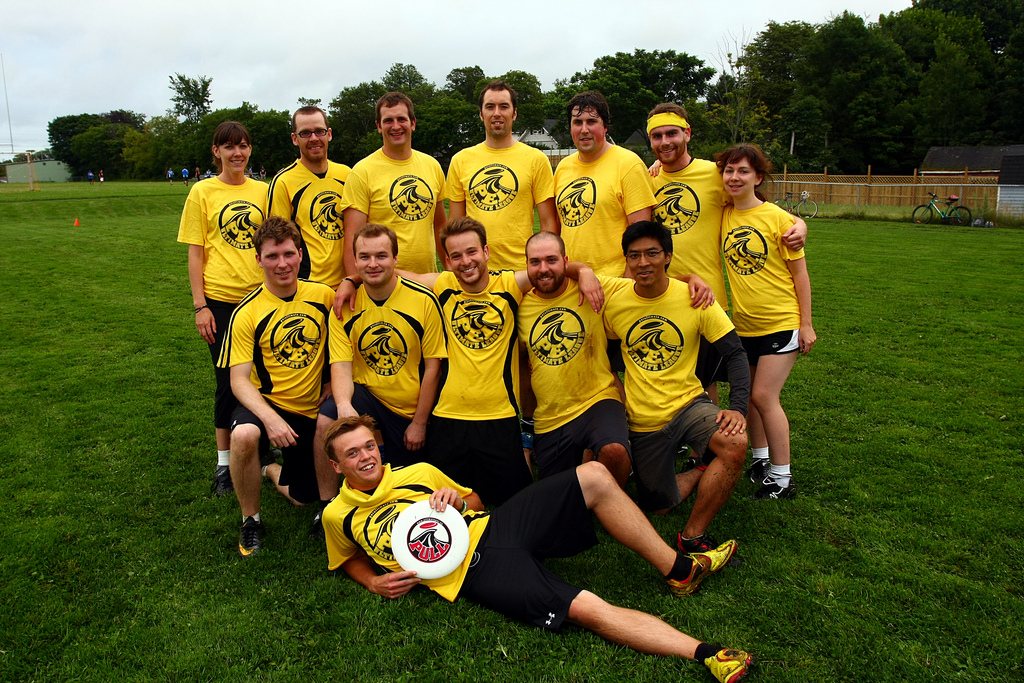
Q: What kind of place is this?
A: It is a field.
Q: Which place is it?
A: It is a field.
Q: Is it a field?
A: Yes, it is a field.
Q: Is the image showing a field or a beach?
A: It is showing a field.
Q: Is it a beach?
A: No, it is a field.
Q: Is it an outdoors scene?
A: Yes, it is outdoors.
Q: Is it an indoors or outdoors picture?
A: It is outdoors.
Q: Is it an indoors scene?
A: No, it is outdoors.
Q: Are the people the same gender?
A: No, they are both male and female.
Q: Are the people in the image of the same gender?
A: No, they are both male and female.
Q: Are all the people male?
A: No, they are both male and female.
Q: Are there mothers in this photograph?
A: No, there are no mothers.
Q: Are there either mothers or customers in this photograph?
A: No, there are no mothers or customers.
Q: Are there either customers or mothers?
A: No, there are no mothers or customers.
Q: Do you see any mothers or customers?
A: No, there are no mothers or customers.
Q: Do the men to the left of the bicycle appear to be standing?
A: Yes, the men are standing.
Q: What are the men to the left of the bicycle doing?
A: The men are standing.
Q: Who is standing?
A: The men are standing.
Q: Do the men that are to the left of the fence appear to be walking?
A: No, the men are standing.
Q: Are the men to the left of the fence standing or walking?
A: The men are standing.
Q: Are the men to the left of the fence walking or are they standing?
A: The men are standing.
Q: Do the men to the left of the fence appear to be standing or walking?
A: The men are standing.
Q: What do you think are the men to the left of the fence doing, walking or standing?
A: The men are standing.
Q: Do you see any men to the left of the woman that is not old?
A: Yes, there are men to the left of the woman.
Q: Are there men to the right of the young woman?
A: No, the men are to the left of the woman.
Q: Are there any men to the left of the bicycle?
A: Yes, there are men to the left of the bicycle.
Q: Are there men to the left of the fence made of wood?
A: Yes, there are men to the left of the fence.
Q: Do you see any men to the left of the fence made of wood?
A: Yes, there are men to the left of the fence.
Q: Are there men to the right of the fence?
A: No, the men are to the left of the fence.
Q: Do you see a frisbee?
A: Yes, there is a frisbee.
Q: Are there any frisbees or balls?
A: Yes, there is a frisbee.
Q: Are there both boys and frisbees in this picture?
A: Yes, there are both a frisbee and a boy.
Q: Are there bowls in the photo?
A: No, there are no bowls.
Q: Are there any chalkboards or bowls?
A: No, there are no bowls or chalkboards.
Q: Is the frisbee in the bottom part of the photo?
A: Yes, the frisbee is in the bottom of the image.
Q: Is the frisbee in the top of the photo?
A: No, the frisbee is in the bottom of the image.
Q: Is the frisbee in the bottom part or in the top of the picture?
A: The frisbee is in the bottom of the image.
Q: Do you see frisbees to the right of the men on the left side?
A: Yes, there is a frisbee to the right of the men.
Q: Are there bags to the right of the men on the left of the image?
A: No, there is a frisbee to the right of the men.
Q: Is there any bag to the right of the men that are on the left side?
A: No, there is a frisbee to the right of the men.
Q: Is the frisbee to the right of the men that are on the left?
A: Yes, the frisbee is to the right of the men.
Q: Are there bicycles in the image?
A: Yes, there is a bicycle.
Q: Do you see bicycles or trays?
A: Yes, there is a bicycle.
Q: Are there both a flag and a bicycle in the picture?
A: No, there is a bicycle but no flags.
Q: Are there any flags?
A: No, there are no flags.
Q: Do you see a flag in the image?
A: No, there are no flags.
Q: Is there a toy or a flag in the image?
A: No, there are no flags or toys.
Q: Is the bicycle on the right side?
A: Yes, the bicycle is on the right of the image.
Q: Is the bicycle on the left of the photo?
A: No, the bicycle is on the right of the image.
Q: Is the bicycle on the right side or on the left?
A: The bicycle is on the right of the image.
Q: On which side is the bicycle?
A: The bicycle is on the right of the image.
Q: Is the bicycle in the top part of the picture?
A: Yes, the bicycle is in the top of the image.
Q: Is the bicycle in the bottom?
A: No, the bicycle is in the top of the image.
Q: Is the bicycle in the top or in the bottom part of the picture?
A: The bicycle is in the top of the image.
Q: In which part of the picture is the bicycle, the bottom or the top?
A: The bicycle is in the top of the image.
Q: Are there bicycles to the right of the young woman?
A: Yes, there is a bicycle to the right of the woman.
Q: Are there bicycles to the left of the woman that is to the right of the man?
A: No, the bicycle is to the right of the woman.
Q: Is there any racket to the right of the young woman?
A: No, there is a bicycle to the right of the woman.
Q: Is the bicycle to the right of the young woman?
A: Yes, the bicycle is to the right of the woman.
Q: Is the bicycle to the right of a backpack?
A: No, the bicycle is to the right of the woman.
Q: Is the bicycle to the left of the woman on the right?
A: No, the bicycle is to the right of the woman.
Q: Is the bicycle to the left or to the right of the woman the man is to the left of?
A: The bicycle is to the right of the woman.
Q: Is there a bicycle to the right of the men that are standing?
A: Yes, there is a bicycle to the right of the men.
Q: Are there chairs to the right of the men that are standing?
A: No, there is a bicycle to the right of the men.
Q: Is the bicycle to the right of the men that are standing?
A: Yes, the bicycle is to the right of the men.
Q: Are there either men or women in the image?
A: Yes, there is a woman.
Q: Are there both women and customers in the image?
A: No, there is a woman but no customers.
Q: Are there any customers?
A: No, there are no customers.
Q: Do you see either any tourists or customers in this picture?
A: No, there are no customers or tourists.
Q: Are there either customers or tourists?
A: No, there are no customers or tourists.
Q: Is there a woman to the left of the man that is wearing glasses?
A: Yes, there is a woman to the left of the man.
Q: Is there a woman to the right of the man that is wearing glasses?
A: No, the woman is to the left of the man.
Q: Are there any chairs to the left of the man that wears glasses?
A: No, there is a woman to the left of the man.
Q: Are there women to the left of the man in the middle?
A: Yes, there is a woman to the left of the man.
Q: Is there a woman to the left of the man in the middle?
A: Yes, there is a woman to the left of the man.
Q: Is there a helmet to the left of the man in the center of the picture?
A: No, there is a woman to the left of the man.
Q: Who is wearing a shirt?
A: The woman is wearing a shirt.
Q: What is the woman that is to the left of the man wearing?
A: The woman is wearing a shirt.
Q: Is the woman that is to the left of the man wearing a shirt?
A: Yes, the woman is wearing a shirt.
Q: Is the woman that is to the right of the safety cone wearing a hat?
A: No, the woman is wearing a shirt.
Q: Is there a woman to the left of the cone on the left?
A: No, the woman is to the right of the cone.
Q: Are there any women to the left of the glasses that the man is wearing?
A: Yes, there is a woman to the left of the glasses.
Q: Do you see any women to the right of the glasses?
A: No, the woman is to the left of the glasses.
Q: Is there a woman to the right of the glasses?
A: No, the woman is to the left of the glasses.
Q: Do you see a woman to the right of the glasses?
A: No, the woman is to the left of the glasses.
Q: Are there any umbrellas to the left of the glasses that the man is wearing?
A: No, there is a woman to the left of the glasses.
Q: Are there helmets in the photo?
A: No, there are no helmets.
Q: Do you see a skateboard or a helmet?
A: No, there are no helmets or skateboards.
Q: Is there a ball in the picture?
A: No, there are no balls.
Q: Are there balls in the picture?
A: No, there are no balls.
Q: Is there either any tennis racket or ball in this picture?
A: No, there are no balls or rackets.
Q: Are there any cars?
A: No, there are no cars.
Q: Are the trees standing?
A: Yes, the trees are standing.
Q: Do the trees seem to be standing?
A: Yes, the trees are standing.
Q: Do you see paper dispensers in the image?
A: No, there are no paper dispensers.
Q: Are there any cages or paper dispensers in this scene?
A: No, there are no paper dispensers or cages.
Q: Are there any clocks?
A: No, there are no clocks.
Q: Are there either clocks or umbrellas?
A: No, there are no clocks or umbrellas.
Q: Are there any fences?
A: Yes, there is a fence.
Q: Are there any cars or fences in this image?
A: Yes, there is a fence.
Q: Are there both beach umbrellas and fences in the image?
A: No, there is a fence but no beach umbrellas.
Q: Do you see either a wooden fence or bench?
A: Yes, there is a wood fence.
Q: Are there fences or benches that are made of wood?
A: Yes, the fence is made of wood.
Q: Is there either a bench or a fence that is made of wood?
A: Yes, the fence is made of wood.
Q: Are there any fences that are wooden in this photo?
A: Yes, there is a wood fence.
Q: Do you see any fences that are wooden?
A: Yes, there is a wood fence.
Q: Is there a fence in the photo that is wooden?
A: Yes, there is a fence that is wooden.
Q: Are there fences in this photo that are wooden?
A: Yes, there is a fence that is wooden.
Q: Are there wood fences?
A: Yes, there is a fence that is made of wood.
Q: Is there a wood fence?
A: Yes, there is a fence that is made of wood.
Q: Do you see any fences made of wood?
A: Yes, there is a fence that is made of wood.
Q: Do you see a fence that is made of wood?
A: Yes, there is a fence that is made of wood.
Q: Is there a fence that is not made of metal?
A: Yes, there is a fence that is made of wood.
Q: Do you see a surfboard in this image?
A: No, there are no surfboards.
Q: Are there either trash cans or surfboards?
A: No, there are no surfboards or trash cans.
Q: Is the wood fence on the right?
A: Yes, the fence is on the right of the image.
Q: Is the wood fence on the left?
A: No, the fence is on the right of the image.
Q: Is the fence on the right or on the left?
A: The fence is on the right of the image.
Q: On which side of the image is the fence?
A: The fence is on the right of the image.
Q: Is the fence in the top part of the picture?
A: Yes, the fence is in the top of the image.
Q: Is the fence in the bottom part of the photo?
A: No, the fence is in the top of the image.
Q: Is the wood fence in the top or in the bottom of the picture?
A: The fence is in the top of the image.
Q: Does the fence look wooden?
A: Yes, the fence is wooden.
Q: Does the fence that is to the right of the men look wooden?
A: Yes, the fence is wooden.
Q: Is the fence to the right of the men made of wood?
A: Yes, the fence is made of wood.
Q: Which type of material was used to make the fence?
A: The fence is made of wood.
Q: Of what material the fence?
A: The fence is made of wood.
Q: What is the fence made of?
A: The fence is made of wood.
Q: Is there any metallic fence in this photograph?
A: No, there is a fence but it is wooden.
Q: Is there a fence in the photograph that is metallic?
A: No, there is a fence but it is wooden.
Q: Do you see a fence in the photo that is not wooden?
A: No, there is a fence but it is wooden.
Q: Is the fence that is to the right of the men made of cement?
A: No, the fence is made of wood.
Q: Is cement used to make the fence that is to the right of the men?
A: No, the fence is made of wood.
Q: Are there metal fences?
A: No, there is a fence but it is made of wood.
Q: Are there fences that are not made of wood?
A: No, there is a fence but it is made of wood.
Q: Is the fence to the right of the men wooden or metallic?
A: The fence is wooden.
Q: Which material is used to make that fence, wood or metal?
A: The fence is made of wood.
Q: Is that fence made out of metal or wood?
A: The fence is made of wood.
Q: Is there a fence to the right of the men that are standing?
A: Yes, there is a fence to the right of the men.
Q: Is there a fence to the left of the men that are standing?
A: No, the fence is to the right of the men.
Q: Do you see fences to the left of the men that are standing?
A: No, the fence is to the right of the men.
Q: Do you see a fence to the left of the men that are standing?
A: No, the fence is to the right of the men.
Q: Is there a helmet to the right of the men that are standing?
A: No, there is a fence to the right of the men.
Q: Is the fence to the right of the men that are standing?
A: Yes, the fence is to the right of the men.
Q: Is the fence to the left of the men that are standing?
A: No, the fence is to the right of the men.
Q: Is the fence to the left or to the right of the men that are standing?
A: The fence is to the right of the men.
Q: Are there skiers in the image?
A: No, there are no skiers.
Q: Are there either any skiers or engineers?
A: No, there are no skiers or engineers.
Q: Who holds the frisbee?
A: The boy holds the frisbee.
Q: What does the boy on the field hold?
A: The boy holds the frisbee.